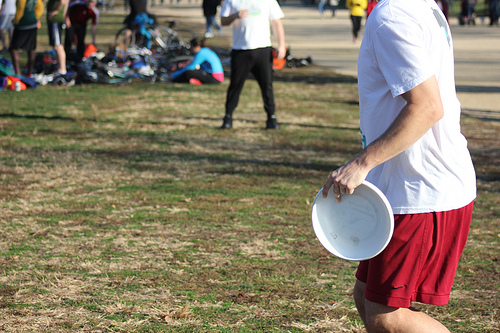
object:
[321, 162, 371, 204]
hand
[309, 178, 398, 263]
frisbee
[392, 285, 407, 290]
black logo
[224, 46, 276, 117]
black pants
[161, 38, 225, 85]
woman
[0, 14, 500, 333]
ground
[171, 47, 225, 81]
blue top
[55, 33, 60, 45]
white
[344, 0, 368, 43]
jogger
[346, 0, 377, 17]
yellow jacket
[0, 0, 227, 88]
crowd of people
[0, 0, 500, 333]
park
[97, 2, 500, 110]
paved pathway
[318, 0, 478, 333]
man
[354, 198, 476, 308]
shorts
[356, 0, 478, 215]
white shirt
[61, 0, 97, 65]
people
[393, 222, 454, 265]
red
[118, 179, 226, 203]
green grass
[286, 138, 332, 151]
brown grass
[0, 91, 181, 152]
grass